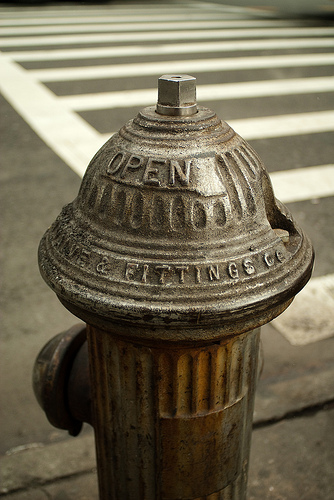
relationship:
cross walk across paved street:
[0, 0, 333, 346] [0, 2, 333, 498]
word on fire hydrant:
[104, 154, 197, 186] [32, 72, 315, 500]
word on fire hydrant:
[118, 251, 268, 286] [32, 72, 315, 500]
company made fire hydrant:
[53, 241, 289, 285] [32, 72, 315, 500]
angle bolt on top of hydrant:
[156, 72, 197, 117] [78, 83, 294, 471]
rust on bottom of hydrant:
[141, 361, 250, 473] [45, 62, 318, 459]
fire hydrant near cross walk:
[32, 72, 315, 500] [24, 12, 327, 259]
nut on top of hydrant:
[158, 80, 195, 104] [37, 115, 314, 498]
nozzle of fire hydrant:
[26, 321, 92, 438] [32, 73, 319, 499]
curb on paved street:
[2, 366, 331, 495] [0, 2, 333, 498]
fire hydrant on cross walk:
[32, 73, 319, 499] [0, 0, 333, 346]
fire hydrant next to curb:
[32, 73, 319, 499] [2, 366, 331, 495]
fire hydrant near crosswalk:
[32, 72, 315, 500] [0, 4, 333, 347]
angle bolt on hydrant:
[153, 70, 204, 116] [109, 61, 301, 347]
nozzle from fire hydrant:
[32, 321, 92, 437] [32, 72, 315, 500]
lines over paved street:
[6, 3, 333, 349] [1, 2, 332, 498]